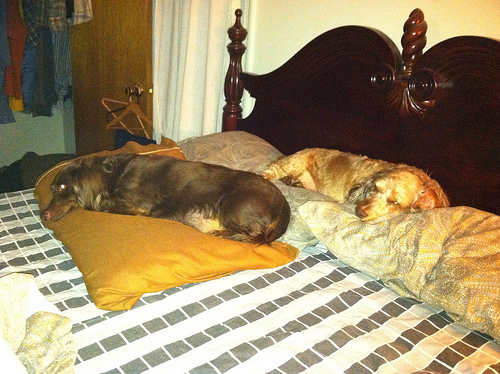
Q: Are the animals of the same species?
A: Yes, all the animals are dogs.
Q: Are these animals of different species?
A: No, all the animals are dogs.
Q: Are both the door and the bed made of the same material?
A: Yes, both the door and the bed are made of wood.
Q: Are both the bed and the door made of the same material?
A: Yes, both the bed and the door are made of wood.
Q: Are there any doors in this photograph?
A: Yes, there is a door.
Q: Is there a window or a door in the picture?
A: Yes, there is a door.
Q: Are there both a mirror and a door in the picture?
A: No, there is a door but no mirrors.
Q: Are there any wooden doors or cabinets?
A: Yes, there is a wood door.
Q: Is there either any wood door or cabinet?
A: Yes, there is a wood door.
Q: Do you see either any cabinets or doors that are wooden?
A: Yes, the door is wooden.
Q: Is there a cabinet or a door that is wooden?
A: Yes, the door is wooden.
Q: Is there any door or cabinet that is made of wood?
A: Yes, the door is made of wood.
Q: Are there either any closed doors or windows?
A: Yes, there is a closed door.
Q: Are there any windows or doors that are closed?
A: Yes, the door is closed.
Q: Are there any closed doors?
A: Yes, there is a closed door.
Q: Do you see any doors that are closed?
A: Yes, there is a closed door.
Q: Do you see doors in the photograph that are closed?
A: Yes, there is a door that is closed.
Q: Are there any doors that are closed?
A: Yes, there is a door that is closed.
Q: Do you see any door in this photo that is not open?
A: Yes, there is an closed door.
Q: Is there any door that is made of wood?
A: Yes, there is a door that is made of wood.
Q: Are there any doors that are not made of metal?
A: Yes, there is a door that is made of wood.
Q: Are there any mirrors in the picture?
A: No, there are no mirrors.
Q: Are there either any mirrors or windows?
A: No, there are no mirrors or windows.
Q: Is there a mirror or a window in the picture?
A: No, there are no mirrors or windows.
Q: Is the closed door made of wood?
A: Yes, the door is made of wood.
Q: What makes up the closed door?
A: The door is made of wood.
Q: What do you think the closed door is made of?
A: The door is made of wood.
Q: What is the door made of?
A: The door is made of wood.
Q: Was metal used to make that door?
A: No, the door is made of wood.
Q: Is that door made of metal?
A: No, the door is made of wood.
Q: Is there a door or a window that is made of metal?
A: No, there is a door but it is made of wood.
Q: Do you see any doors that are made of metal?
A: No, there is a door but it is made of wood.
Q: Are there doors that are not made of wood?
A: No, there is a door but it is made of wood.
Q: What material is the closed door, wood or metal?
A: The door is made of wood.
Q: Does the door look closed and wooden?
A: Yes, the door is closed and wooden.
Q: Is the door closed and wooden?
A: Yes, the door is closed and wooden.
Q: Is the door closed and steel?
A: No, the door is closed but wooden.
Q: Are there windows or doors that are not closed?
A: No, there is a door but it is closed.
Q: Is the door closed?
A: Yes, the door is closed.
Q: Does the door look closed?
A: Yes, the door is closed.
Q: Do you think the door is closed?
A: Yes, the door is closed.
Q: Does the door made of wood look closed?
A: Yes, the door is closed.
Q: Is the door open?
A: No, the door is closed.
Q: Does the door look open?
A: No, the door is closed.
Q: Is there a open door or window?
A: No, there is a door but it is closed.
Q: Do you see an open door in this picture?
A: No, there is a door but it is closed.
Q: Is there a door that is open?
A: No, there is a door but it is closed.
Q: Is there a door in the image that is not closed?
A: No, there is a door but it is closed.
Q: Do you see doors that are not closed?
A: No, there is a door but it is closed.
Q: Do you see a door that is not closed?
A: No, there is a door but it is closed.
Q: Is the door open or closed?
A: The door is closed.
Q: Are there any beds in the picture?
A: Yes, there is a bed.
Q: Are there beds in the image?
A: Yes, there is a bed.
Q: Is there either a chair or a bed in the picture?
A: Yes, there is a bed.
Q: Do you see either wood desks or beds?
A: Yes, there is a wood bed.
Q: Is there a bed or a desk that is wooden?
A: Yes, the bed is wooden.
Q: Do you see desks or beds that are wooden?
A: Yes, the bed is wooden.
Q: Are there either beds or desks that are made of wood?
A: Yes, the bed is made of wood.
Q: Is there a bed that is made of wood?
A: Yes, there is a bed that is made of wood.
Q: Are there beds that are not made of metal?
A: Yes, there is a bed that is made of wood.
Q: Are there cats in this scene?
A: No, there are no cats.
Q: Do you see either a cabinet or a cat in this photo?
A: No, there are no cats or cabinets.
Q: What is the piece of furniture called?
A: The piece of furniture is a bed.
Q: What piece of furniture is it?
A: The piece of furniture is a bed.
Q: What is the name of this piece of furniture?
A: This is a bed.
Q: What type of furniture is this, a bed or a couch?
A: This is a bed.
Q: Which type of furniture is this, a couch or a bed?
A: This is a bed.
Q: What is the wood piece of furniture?
A: The piece of furniture is a bed.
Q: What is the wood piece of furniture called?
A: The piece of furniture is a bed.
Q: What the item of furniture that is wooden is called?
A: The piece of furniture is a bed.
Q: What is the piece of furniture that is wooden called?
A: The piece of furniture is a bed.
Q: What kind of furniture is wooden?
A: The furniture is a bed.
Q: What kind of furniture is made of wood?
A: The furniture is a bed.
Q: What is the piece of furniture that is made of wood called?
A: The piece of furniture is a bed.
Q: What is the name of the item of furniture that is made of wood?
A: The piece of furniture is a bed.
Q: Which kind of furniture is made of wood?
A: The furniture is a bed.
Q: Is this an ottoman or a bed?
A: This is a bed.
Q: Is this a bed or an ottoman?
A: This is a bed.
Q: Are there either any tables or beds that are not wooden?
A: No, there is a bed but it is wooden.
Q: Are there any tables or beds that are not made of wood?
A: No, there is a bed but it is made of wood.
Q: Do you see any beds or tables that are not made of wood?
A: No, there is a bed but it is made of wood.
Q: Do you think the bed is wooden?
A: Yes, the bed is wooden.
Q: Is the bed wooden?
A: Yes, the bed is wooden.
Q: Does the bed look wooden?
A: Yes, the bed is wooden.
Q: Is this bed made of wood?
A: Yes, the bed is made of wood.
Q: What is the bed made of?
A: The bed is made of wood.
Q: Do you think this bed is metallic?
A: No, the bed is wooden.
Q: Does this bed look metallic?
A: No, the bed is wooden.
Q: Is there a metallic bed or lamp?
A: No, there is a bed but it is wooden.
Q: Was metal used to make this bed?
A: No, the bed is made of wood.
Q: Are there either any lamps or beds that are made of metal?
A: No, there is a bed but it is made of wood.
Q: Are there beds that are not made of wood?
A: No, there is a bed but it is made of wood.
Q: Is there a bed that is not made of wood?
A: No, there is a bed but it is made of wood.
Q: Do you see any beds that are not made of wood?
A: No, there is a bed but it is made of wood.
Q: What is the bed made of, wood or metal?
A: The bed is made of wood.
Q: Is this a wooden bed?
A: Yes, this is a wooden bed.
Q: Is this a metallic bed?
A: No, this is a wooden bed.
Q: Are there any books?
A: No, there are no books.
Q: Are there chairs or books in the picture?
A: No, there are no books or chairs.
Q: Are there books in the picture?
A: No, there are no books.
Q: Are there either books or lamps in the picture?
A: No, there are no books or lamps.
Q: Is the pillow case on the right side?
A: Yes, the pillow case is on the right of the image.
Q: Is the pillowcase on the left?
A: No, the pillowcase is on the right of the image.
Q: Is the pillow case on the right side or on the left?
A: The pillow case is on the right of the image.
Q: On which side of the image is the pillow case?
A: The pillow case is on the right of the image.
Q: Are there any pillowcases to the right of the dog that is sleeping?
A: Yes, there is a pillowcase to the right of the dog.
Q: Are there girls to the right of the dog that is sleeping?
A: No, there is a pillowcase to the right of the dog.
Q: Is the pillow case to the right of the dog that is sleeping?
A: Yes, the pillow case is to the right of the dog.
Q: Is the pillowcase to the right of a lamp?
A: No, the pillowcase is to the right of the dog.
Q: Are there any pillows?
A: Yes, there is a pillow.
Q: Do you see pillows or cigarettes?
A: Yes, there is a pillow.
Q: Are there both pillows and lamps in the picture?
A: No, there is a pillow but no lamps.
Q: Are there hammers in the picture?
A: No, there are no hammers.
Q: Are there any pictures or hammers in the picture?
A: No, there are no hammers or pictures.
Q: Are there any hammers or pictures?
A: No, there are no hammers or pictures.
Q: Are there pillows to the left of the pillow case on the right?
A: Yes, there is a pillow to the left of the pillowcase.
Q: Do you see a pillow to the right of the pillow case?
A: No, the pillow is to the left of the pillow case.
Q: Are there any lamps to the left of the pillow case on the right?
A: No, there is a pillow to the left of the pillow case.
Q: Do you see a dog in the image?
A: Yes, there is a dog.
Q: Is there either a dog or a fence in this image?
A: Yes, there is a dog.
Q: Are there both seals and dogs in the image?
A: No, there is a dog but no seals.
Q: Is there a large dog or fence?
A: Yes, there is a large dog.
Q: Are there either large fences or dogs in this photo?
A: Yes, there is a large dog.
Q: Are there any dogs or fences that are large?
A: Yes, the dog is large.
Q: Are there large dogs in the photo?
A: Yes, there is a large dog.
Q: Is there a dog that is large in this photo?
A: Yes, there is a large dog.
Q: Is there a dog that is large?
A: Yes, there is a dog that is large.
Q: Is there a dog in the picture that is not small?
A: Yes, there is a large dog.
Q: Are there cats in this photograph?
A: No, there are no cats.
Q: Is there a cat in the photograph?
A: No, there are no cats.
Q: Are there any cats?
A: No, there are no cats.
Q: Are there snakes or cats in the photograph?
A: No, there are no cats or snakes.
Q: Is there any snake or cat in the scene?
A: No, there are no cats or snakes.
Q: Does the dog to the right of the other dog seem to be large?
A: Yes, the dog is large.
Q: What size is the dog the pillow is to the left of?
A: The dog is large.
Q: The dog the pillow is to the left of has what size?
A: The dog is large.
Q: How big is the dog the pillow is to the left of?
A: The dog is large.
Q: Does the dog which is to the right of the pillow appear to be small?
A: No, the dog is large.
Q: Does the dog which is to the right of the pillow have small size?
A: No, the dog is large.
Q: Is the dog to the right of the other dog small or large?
A: The dog is large.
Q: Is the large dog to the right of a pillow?
A: Yes, the dog is to the right of a pillow.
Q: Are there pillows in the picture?
A: Yes, there is a pillow.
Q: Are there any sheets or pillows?
A: Yes, there is a pillow.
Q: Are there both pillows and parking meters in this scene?
A: No, there is a pillow but no parking meters.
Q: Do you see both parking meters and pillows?
A: No, there is a pillow but no parking meters.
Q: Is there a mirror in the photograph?
A: No, there are no mirrors.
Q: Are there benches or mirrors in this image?
A: No, there are no mirrors or benches.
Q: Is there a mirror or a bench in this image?
A: No, there are no mirrors or benches.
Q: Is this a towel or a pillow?
A: This is a pillow.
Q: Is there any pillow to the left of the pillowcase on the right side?
A: Yes, there is a pillow to the left of the pillowcase.